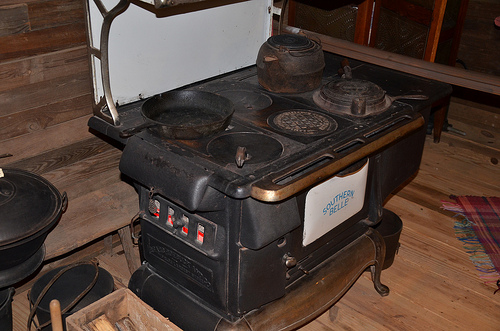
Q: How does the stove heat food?
A: With wood.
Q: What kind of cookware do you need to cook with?
A: Cast Iron.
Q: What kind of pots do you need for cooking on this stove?
A: Cast Iron.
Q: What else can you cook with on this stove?
A: A black kettle.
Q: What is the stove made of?
A: Cast iron.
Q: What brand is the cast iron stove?
A: Southern Belle.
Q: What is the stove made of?
A: Cast iron.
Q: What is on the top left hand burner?
A: Cast iron pan.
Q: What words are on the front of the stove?
A: Southern Belle.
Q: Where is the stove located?
A: In a cabin.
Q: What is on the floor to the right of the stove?
A: Rug.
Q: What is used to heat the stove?
A: Wood.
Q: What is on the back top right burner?
A: A pot.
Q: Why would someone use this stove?
A: To cook with.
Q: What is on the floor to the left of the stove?
A: Pot.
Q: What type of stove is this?
A: Wood-burning.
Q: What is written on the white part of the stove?
A: Southern Belle.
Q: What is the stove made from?
A: Cast iron.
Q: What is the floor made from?
A: Wood.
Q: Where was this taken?
A: In the kitchen.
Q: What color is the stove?
A: Black.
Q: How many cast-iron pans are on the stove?
A: One.